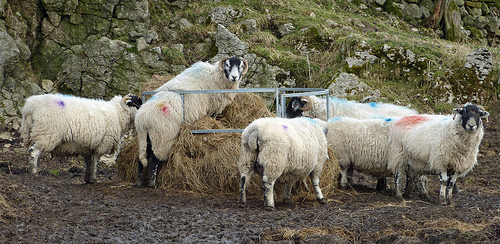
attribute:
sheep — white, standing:
[12, 97, 133, 182]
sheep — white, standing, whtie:
[120, 50, 246, 168]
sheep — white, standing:
[244, 92, 335, 206]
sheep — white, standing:
[397, 99, 499, 176]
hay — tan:
[191, 159, 229, 188]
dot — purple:
[52, 98, 68, 112]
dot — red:
[156, 103, 169, 123]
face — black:
[215, 49, 245, 93]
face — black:
[454, 97, 483, 135]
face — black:
[289, 93, 305, 113]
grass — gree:
[353, 23, 389, 45]